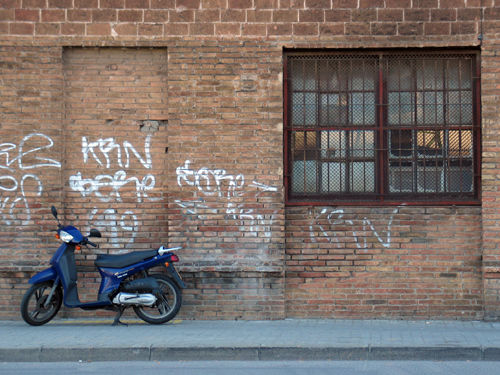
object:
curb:
[4, 319, 499, 364]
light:
[59, 229, 74, 244]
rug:
[94, 250, 157, 269]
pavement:
[0, 318, 496, 373]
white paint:
[177, 201, 274, 303]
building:
[2, 1, 498, 321]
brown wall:
[0, 0, 499, 321]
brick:
[449, 20, 478, 35]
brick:
[396, 21, 425, 32]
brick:
[344, 21, 370, 36]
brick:
[270, 23, 292, 36]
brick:
[165, 23, 190, 35]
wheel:
[132, 274, 183, 324]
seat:
[94, 249, 157, 269]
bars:
[283, 49, 480, 206]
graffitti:
[1, 131, 406, 258]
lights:
[172, 254, 180, 261]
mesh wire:
[286, 48, 480, 208]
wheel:
[20, 279, 64, 326]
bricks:
[111, 21, 138, 37]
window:
[287, 54, 478, 200]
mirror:
[51, 205, 58, 216]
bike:
[20, 205, 187, 327]